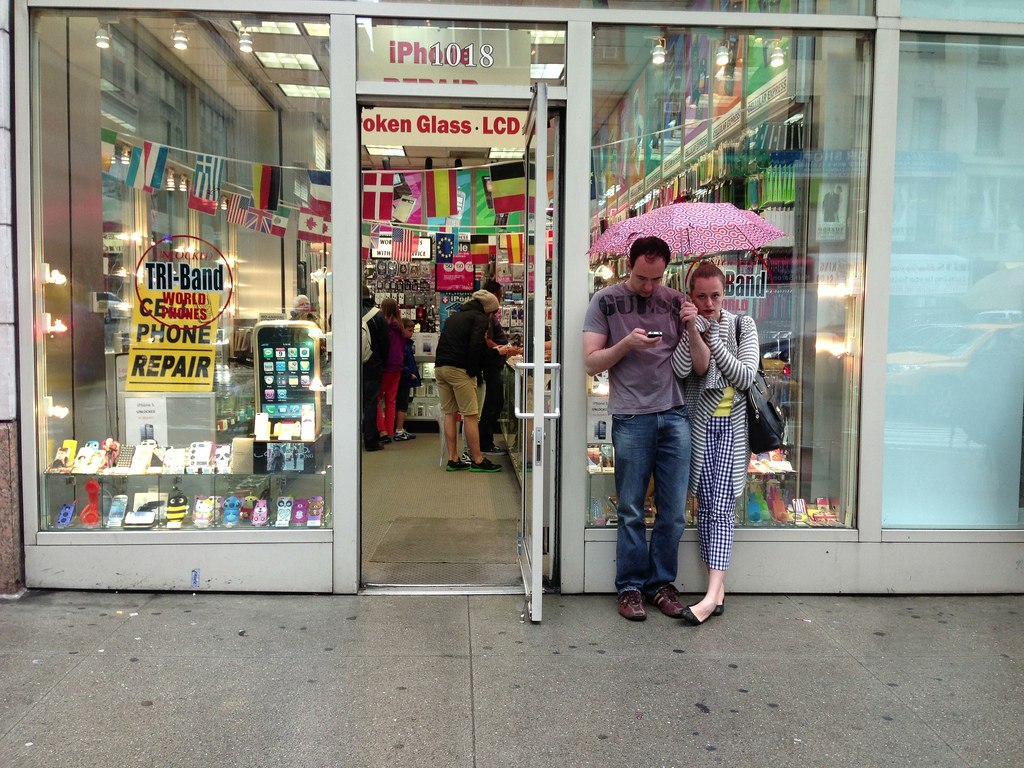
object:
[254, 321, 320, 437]
cell phone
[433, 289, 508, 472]
person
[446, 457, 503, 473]
shoes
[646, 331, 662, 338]
phone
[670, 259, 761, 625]
woman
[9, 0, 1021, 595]
store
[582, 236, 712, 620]
man